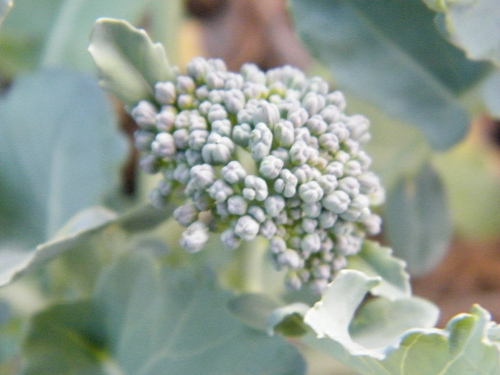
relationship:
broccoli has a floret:
[129, 55, 384, 295] [246, 124, 272, 158]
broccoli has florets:
[129, 55, 384, 295] [272, 117, 295, 148]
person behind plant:
[187, 3, 233, 22] [83, 14, 415, 317]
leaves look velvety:
[86, 15, 176, 109] [86, 17, 180, 106]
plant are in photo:
[83, 14, 415, 317] [2, 2, 499, 374]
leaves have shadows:
[86, 15, 176, 109] [113, 204, 170, 235]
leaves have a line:
[86, 15, 176, 109] [101, 24, 158, 105]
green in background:
[3, 2, 179, 78] [186, 2, 314, 73]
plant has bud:
[83, 14, 415, 317] [200, 130, 238, 166]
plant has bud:
[83, 14, 415, 317] [189, 161, 216, 192]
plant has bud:
[83, 14, 415, 317] [219, 158, 248, 185]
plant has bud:
[83, 14, 415, 317] [259, 154, 287, 179]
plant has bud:
[83, 14, 415, 317] [240, 173, 271, 204]